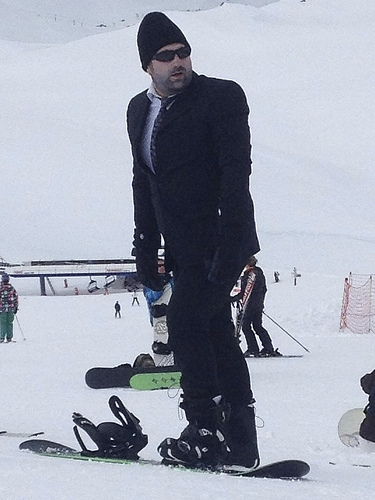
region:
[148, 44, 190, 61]
A pair of black sun glasses.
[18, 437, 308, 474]
A black and green snow board.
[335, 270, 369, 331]
A red fence in distance.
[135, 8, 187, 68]
A black knit cap.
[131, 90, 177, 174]
A dark colored tie.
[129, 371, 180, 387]
A light green snow board.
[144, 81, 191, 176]
A white shirt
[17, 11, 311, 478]
Men wearing a suit stepping onto a snowoard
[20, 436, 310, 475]
Snowboard in the snow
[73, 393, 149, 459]
Black binding on the snowboard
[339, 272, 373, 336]
Red fencing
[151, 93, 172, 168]
Tie around the man's neck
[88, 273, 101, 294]
Empty chair on chair lift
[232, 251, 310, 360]
Man on skis holding ski pole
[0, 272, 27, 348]
Person in green snow pants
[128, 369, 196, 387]
Green snowboard on the snow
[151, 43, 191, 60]
Sunglasses over man's eyes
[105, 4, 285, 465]
man wearing business suit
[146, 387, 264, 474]
black ski boots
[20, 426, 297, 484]
black snowboard on the snow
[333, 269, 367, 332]
orange netting on the mountain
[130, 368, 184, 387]
green snowboard laying on the snow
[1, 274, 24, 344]
person wearing patterned coat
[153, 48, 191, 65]
black sunglasses man is wearing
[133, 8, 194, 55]
black knit cap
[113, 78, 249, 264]
black jacket man is wearing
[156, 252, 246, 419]
black pants man is wearing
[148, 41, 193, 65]
A pair of black sunglasses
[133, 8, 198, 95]
Black hat on man's head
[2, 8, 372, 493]
Man standing on white snow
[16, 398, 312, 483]
Two boots on a black snowboard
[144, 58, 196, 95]
Facial hair on man's face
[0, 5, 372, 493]
Many people are at a ski slope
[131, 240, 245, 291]
A pair of black gloves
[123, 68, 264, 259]
The coat is black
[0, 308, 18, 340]
A pair of green ski pants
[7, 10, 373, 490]
a scene during the day time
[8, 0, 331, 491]
a scene outside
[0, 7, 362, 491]
an image at the ski resort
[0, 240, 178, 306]
a ski lift in the distance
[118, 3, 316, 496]
a skier looking right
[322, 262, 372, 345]
a orange fence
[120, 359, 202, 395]
a green ski board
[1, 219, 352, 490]
skiers in the background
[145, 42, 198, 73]
shades on face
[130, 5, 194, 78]
cap on head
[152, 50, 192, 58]
The black sunglasses the man is wearing.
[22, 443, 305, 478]
The snowboard the man in the sunglasses is standing near.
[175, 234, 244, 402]
The black pants the man in the sunglasses is wearing.